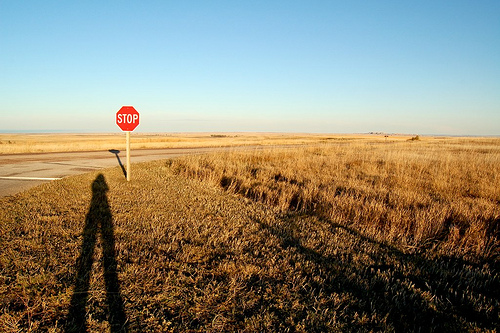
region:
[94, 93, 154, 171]
red and white sign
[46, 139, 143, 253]
shadow on the ground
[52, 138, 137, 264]
shadow of a person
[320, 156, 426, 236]
brown field next to shadow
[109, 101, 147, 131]
the word "stop" on sign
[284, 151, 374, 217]
gold grass in the field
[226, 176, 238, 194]
small cluster of grass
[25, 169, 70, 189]
white line on the street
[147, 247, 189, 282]
black color on the brown grass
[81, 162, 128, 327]
long shadow cast on the grass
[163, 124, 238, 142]
open field of grass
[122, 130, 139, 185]
tall brown pole on side of road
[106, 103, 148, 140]
large red sign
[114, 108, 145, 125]
white words on the pole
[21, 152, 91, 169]
brown dirt on the road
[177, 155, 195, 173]
tall brown grass on ground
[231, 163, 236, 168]
tall brown grass on ground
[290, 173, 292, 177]
tall brown grass on ground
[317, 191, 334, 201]
tall brown grass on ground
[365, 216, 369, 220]
tall brown grass on ground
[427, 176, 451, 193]
tall brown grass on ground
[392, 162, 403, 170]
tall brown grass on ground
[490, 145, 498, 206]
tall brown grass on ground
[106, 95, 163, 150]
A red stop sign.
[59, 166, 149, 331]
Long shadow of a person.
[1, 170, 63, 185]
White line on paved road.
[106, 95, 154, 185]
Sign with written words on it.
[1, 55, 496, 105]
A light blue cloudless sky.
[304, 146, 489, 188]
Wheat in a field.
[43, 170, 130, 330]
The shadow of a woman.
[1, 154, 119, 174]
A grey paved road.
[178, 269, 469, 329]
Tan and brown grassy field.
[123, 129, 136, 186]
A small wooden pole under a sign.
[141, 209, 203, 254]
the grass is tall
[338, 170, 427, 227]
the hay is brown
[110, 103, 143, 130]
a stop sign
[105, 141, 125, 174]
a shadow on the stop sign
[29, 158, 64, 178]
the road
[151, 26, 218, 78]
a clear sky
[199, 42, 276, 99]
the sky is clear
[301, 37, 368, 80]
a blue clear sky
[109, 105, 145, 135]
red and white sign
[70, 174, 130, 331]
A tall black shadow of a person.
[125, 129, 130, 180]
Grey metal pole of the stop sign.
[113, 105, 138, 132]
Red and white octagon stop sign.